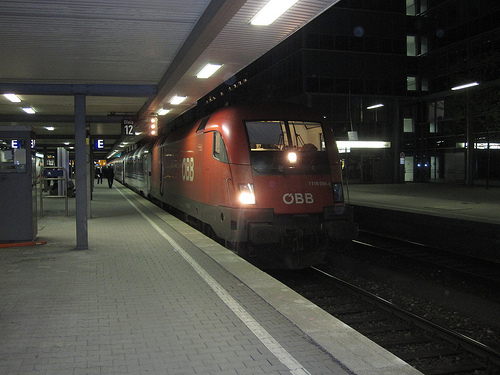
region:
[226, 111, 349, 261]
the front of the train has two illuminated lights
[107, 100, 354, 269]
a red and silver train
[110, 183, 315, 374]
a white line on the walkway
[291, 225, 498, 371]
two train tracks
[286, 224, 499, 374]
gravels are around tracks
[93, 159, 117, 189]
people walking on the walkway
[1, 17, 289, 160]
lights on the ceiling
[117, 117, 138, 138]
a black sign with the number 12 in white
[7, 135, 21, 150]
an illuminated E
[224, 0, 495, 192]
a building with many windows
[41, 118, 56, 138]
light at train station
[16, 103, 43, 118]
light at train station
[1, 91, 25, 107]
light at train station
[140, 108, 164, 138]
light at train station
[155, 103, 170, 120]
light at train station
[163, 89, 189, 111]
light at train station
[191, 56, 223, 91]
light at train station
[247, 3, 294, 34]
light at train station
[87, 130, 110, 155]
light at train station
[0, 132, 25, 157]
light at train station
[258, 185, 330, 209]
white lettering on the train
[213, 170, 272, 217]
right light is bright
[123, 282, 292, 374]
white line on the platform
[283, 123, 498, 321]
train is on the track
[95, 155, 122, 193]
people gathered in the rear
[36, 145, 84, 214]
gate is silver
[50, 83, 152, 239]
pole and partition are blue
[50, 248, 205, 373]
floor is white brick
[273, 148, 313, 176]
light on the windsheild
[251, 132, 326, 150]
wipers are black on window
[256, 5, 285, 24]
light on ceiling is on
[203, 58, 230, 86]
light on ceiling is on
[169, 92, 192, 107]
light on ceiling is on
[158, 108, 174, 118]
light on ceiling is on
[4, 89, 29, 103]
light on ceiling is on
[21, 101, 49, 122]
light on ceiling is on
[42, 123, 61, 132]
light on ceiling is on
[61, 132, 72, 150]
light on ceiling is on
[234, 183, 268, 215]
headlight is on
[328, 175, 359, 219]
headlight is off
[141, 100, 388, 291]
subway on the tracks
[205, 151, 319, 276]
subway has it's lights on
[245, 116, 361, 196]
windows on the subway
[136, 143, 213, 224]
doors on the subway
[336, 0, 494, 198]
building next to the tracks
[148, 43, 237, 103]
lights above the subway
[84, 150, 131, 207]
people waiting to get on the subway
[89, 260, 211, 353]
bricks on the ground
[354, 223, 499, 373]
tracks for the train to go on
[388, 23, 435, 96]
windows on the buildings